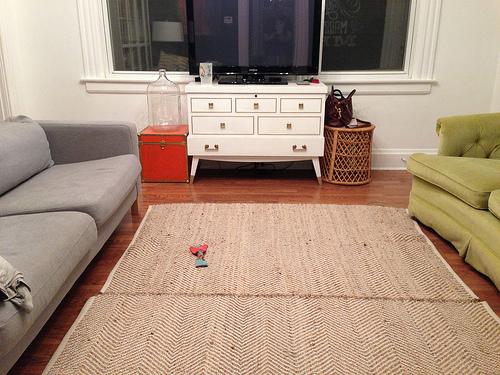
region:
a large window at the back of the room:
[100, 0, 418, 77]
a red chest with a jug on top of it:
[135, 63, 193, 185]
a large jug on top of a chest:
[143, 66, 182, 133]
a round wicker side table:
[325, 120, 375, 186]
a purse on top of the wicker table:
[323, 83, 371, 133]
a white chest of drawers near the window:
[185, 73, 329, 188]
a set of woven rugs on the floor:
[38, 200, 498, 374]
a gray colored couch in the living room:
[0, 110, 149, 374]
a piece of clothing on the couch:
[0, 253, 42, 317]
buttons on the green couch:
[456, 130, 498, 160]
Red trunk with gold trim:
[138, 124, 191, 185]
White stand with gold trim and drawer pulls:
[186, 87, 325, 185]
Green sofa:
[405, 114, 497, 289]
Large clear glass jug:
[145, 67, 182, 130]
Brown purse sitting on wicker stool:
[328, 84, 358, 129]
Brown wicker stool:
[325, 120, 377, 189]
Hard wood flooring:
[162, 180, 405, 201]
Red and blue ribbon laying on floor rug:
[186, 239, 213, 271]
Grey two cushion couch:
[0, 113, 146, 367]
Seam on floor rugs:
[100, 284, 480, 307]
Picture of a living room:
[3, 11, 493, 358]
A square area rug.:
[76, 195, 499, 368]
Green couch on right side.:
[397, 91, 499, 285]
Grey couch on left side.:
[6, 108, 141, 358]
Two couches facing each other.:
[8, 93, 498, 364]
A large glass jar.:
[143, 63, 181, 132]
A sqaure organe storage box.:
[133, 120, 193, 186]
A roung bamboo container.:
[329, 115, 376, 187]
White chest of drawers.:
[183, 78, 329, 189]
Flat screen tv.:
[178, 5, 327, 75]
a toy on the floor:
[188, 239, 212, 276]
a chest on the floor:
[137, 119, 192, 180]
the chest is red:
[135, 120, 194, 185]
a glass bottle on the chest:
[138, 62, 185, 132]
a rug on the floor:
[35, 180, 499, 371]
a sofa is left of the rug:
[0, 111, 146, 368]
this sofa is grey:
[4, 101, 152, 367]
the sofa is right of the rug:
[400, 87, 498, 302]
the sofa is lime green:
[400, 104, 497, 286]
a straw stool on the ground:
[323, 123, 379, 188]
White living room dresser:
[184, 79, 326, 186]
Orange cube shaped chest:
[135, 121, 190, 182]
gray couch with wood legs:
[0, 112, 142, 372]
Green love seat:
[404, 112, 499, 294]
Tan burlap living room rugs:
[39, 202, 498, 374]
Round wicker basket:
[320, 118, 376, 185]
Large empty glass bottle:
[144, 68, 182, 130]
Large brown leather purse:
[324, 85, 371, 129]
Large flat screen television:
[181, 2, 323, 83]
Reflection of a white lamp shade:
[150, 17, 183, 44]